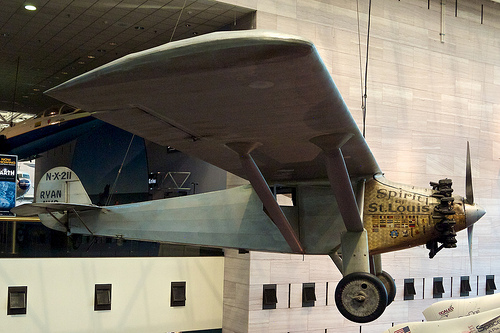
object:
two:
[333, 269, 396, 324]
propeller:
[463, 141, 478, 274]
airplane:
[7, 28, 485, 325]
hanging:
[4, 28, 489, 324]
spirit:
[367, 188, 432, 212]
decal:
[360, 177, 463, 255]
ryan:
[36, 188, 62, 200]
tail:
[29, 100, 148, 320]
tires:
[332, 271, 390, 323]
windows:
[169, 281, 186, 306]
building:
[0, 1, 499, 333]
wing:
[41, 28, 385, 190]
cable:
[363, 1, 376, 139]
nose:
[15, 178, 29, 191]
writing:
[366, 202, 428, 215]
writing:
[36, 189, 64, 200]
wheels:
[334, 273, 387, 325]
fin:
[14, 166, 91, 233]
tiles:
[381, 84, 411, 109]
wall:
[255, 1, 498, 333]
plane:
[0, 104, 93, 161]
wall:
[34, 127, 224, 203]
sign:
[0, 154, 14, 216]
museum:
[0, 0, 499, 332]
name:
[368, 189, 438, 215]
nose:
[363, 166, 487, 256]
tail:
[31, 164, 97, 204]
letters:
[36, 191, 47, 199]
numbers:
[60, 171, 68, 181]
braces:
[223, 132, 363, 254]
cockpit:
[60, 104, 73, 116]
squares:
[91, 284, 113, 311]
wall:
[3, 257, 223, 330]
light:
[17, 2, 38, 12]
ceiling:
[0, 0, 255, 117]